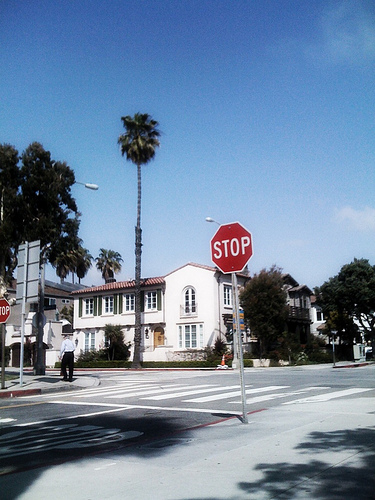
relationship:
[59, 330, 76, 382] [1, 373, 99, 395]
man on sidewalk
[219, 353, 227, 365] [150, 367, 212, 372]
traffic cone on sidewalk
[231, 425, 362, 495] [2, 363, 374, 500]
shadow on road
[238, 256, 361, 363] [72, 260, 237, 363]
trees in front of building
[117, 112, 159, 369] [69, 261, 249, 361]
palm tree in front of building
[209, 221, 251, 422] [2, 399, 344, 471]
stop sign on street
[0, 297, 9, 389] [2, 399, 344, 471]
stop sign on street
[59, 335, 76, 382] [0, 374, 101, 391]
man walking on sidewalk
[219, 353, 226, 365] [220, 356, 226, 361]
orange cone with white strpe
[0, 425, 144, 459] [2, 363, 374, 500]
stop written on road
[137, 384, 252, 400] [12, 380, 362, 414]
white line for street crossing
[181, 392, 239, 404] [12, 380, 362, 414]
white line for street crossing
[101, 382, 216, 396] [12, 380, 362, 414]
white line for street crossing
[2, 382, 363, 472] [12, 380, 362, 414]
road for street crossing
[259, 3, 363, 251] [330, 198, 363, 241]
sky with cloud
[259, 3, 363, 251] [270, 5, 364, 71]
sky with cloud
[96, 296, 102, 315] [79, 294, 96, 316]
shutter on window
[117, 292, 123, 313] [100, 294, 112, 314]
shutter on window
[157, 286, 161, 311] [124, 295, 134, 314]
shutter on window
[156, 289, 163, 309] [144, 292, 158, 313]
shutter on window